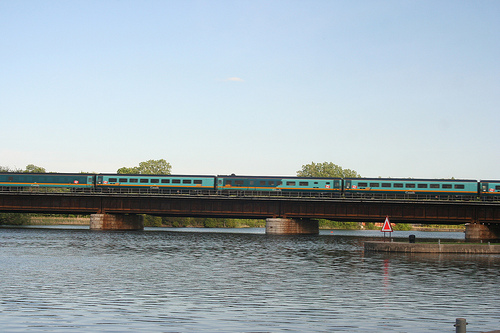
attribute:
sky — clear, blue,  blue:
[2, 3, 499, 173]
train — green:
[89, 146, 497, 211]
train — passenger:
[0, 160, 497, 215]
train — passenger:
[4, 177, 499, 194]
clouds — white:
[17, 68, 487, 146]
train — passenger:
[6, 155, 498, 203]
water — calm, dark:
[78, 227, 322, 316]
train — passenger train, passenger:
[4, 167, 499, 197]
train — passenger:
[2, 170, 497, 202]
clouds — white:
[96, 70, 211, 138]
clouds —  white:
[7, 144, 57, 165]